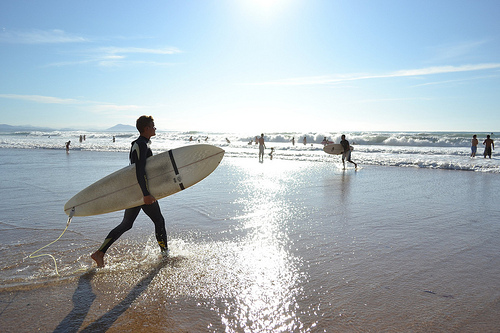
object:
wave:
[222, 153, 498, 173]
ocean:
[2, 127, 498, 326]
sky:
[0, 1, 500, 129]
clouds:
[254, 63, 494, 89]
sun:
[215, 0, 317, 332]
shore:
[3, 206, 498, 321]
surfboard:
[65, 144, 230, 231]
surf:
[186, 134, 310, 211]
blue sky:
[0, 12, 495, 134]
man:
[337, 133, 358, 170]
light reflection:
[206, 142, 343, 331]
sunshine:
[203, 19, 274, 143]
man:
[254, 127, 266, 160]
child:
[269, 147, 276, 158]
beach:
[402, 159, 496, 244]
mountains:
[0, 117, 136, 134]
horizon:
[0, 104, 490, 132]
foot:
[90, 252, 105, 267]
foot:
[162, 247, 178, 262]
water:
[216, 179, 499, 329]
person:
[483, 135, 495, 158]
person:
[469, 132, 481, 155]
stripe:
[167, 151, 184, 191]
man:
[119, 119, 176, 256]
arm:
[134, 153, 156, 207]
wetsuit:
[115, 130, 169, 267]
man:
[77, 117, 181, 269]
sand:
[2, 147, 499, 331]